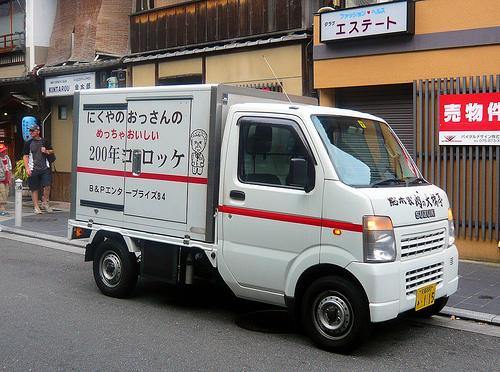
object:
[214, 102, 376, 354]
side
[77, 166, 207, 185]
stripes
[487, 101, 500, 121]
lettering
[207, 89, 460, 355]
front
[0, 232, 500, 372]
asphalt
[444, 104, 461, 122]
lettering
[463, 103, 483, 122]
lettering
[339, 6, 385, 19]
lettering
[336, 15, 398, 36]
lettering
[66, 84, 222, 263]
side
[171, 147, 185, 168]
lettering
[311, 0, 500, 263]
building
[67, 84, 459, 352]
truck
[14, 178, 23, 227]
pole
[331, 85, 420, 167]
gate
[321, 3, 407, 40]
sign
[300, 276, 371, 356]
right tire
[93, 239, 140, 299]
back tire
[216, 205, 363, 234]
stripe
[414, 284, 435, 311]
license plate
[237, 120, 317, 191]
front window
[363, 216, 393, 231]
front lights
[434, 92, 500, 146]
red sign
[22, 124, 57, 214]
man walking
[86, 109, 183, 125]
black lettering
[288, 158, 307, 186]
sideview mirror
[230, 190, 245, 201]
black doorhandle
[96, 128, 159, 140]
red lettering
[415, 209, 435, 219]
brand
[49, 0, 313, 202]
bars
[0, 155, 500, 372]
paved street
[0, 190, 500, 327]
concrete sidewalk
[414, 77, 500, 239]
metal gate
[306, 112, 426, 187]
glass windshield